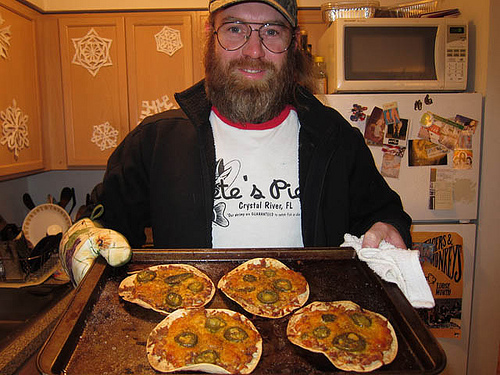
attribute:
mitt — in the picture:
[60, 220, 130, 285]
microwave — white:
[332, 16, 469, 91]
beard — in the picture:
[198, 67, 295, 127]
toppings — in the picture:
[295, 304, 392, 365]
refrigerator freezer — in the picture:
[311, 90, 481, 373]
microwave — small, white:
[316, 19, 470, 94]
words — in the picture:
[218, 160, 308, 227]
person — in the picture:
[116, 1, 396, 248]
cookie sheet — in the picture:
[32, 246, 449, 371]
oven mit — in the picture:
[56, 211, 133, 291]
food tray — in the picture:
[322, 6, 374, 21]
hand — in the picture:
[351, 223, 426, 268]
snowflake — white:
[68, 30, 120, 75]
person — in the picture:
[53, 0, 415, 293]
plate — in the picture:
[6, 204, 71, 233]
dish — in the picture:
[24, 204, 74, 248]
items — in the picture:
[365, 99, 470, 206]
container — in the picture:
[320, 3, 375, 26]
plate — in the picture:
[23, 204, 76, 252]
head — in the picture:
[204, 0, 301, 124]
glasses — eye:
[209, 18, 296, 52]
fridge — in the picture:
[321, 90, 482, 374]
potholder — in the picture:
[22, 181, 188, 354]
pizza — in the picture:
[144, 305, 264, 369]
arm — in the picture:
[341, 126, 413, 257]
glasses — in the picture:
[214, 17, 294, 54]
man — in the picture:
[56, 2, 435, 302]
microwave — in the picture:
[301, 5, 486, 95]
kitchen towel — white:
[337, 228, 438, 310]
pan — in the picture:
[94, 316, 141, 371]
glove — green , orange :
[56, 217, 130, 289]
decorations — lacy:
[41, 11, 189, 166]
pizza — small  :
[278, 304, 398, 374]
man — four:
[58, 2, 413, 287]